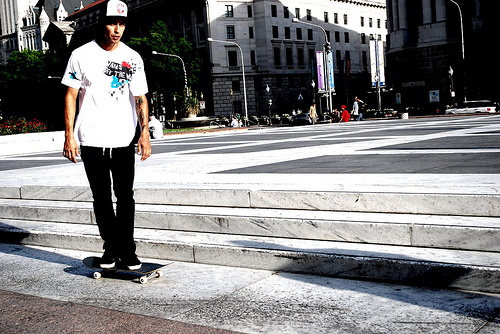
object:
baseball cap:
[96, 0, 131, 18]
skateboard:
[82, 254, 173, 284]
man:
[60, 0, 152, 271]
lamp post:
[51, 74, 64, 82]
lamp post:
[157, 53, 192, 104]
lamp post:
[213, 39, 251, 121]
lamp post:
[299, 20, 335, 117]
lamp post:
[447, 0, 468, 60]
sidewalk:
[0, 241, 500, 333]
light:
[204, 36, 216, 42]